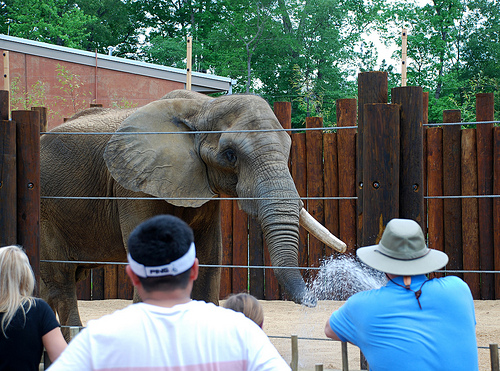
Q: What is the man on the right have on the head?
A: A hat?.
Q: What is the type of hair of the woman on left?
A: Blonde.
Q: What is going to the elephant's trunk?
A: Water.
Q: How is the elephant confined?
A: With a fence.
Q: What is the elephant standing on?
A: Dirt.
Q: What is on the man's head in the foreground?
A: A headband.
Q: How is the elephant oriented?
A: Towards the right?.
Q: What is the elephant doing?
A: Walking forward.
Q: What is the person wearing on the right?
A: An olive green hat.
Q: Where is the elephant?
A: In captivity.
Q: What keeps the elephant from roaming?
A: A wood log fence.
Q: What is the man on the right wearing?
A: A light blue shirt.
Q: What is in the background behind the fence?
A: The tops of green trees.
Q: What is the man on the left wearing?
A: A white shirt.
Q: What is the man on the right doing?
A: Spraying water on an elephant.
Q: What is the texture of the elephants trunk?
A: Ridges.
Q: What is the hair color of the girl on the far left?
A: Blonde.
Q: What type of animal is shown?
A: Elephant.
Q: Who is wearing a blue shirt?
A: Person on the right.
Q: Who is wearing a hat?
A: Man in the blue shirt.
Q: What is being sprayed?
A: Water.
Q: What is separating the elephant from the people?
A: Fence.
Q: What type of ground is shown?
A: Bare.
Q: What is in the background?
A: Trees.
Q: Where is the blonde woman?
A: Left.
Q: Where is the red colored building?
A: Behind the elephant.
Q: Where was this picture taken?
A: At a zoo.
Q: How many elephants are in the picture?
A: One.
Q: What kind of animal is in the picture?
A: An elephant.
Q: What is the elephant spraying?
A: Water.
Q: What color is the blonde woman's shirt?
A: Black.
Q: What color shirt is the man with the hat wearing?
A: Blue.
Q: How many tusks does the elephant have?
A: One.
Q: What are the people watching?
A: An elephant.